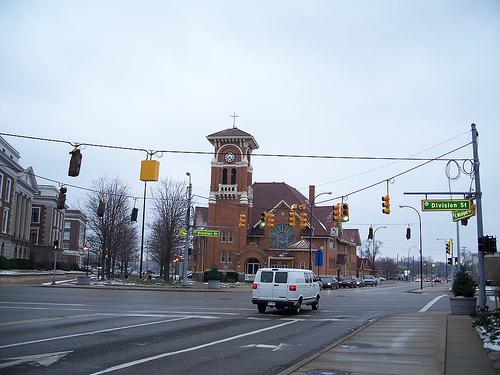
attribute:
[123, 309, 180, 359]
pavement — wet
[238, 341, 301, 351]
arrow — white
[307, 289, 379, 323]
pavement — wet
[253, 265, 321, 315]
van — white, driving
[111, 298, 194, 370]
pavement — wet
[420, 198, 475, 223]
signs — street name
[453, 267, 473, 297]
tree — small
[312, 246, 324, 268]
sign — blue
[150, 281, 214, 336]
pavement — wet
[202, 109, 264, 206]
steeple — church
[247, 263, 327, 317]
van — white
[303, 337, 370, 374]
covers — manhole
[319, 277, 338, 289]
traffic — line, stopped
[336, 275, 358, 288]
traffic — stopped, line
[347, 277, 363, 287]
traffic — stopped, line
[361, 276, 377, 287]
traffic — stopped, line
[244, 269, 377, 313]
traffic — city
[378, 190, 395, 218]
stop light — group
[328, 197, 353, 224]
stop light — group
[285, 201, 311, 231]
stop light — group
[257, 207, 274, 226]
stop light — group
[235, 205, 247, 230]
stop light — group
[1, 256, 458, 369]
street — busy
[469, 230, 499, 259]
light — crosswalk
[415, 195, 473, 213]
sign — division st